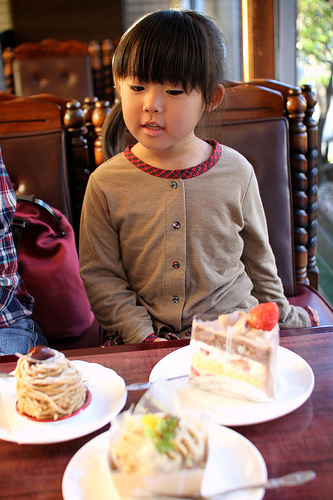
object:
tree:
[297, 0, 333, 162]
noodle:
[9, 348, 90, 415]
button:
[171, 180, 179, 191]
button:
[172, 221, 179, 230]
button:
[173, 261, 180, 270]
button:
[173, 295, 180, 303]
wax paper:
[187, 310, 282, 346]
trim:
[121, 139, 226, 182]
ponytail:
[102, 100, 127, 160]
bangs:
[115, 10, 211, 108]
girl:
[77, 7, 320, 344]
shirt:
[77, 137, 317, 347]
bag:
[13, 195, 112, 348]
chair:
[1, 94, 89, 249]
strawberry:
[245, 301, 279, 330]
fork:
[155, 467, 317, 499]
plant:
[60, 410, 267, 499]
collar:
[123, 134, 222, 181]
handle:
[12, 191, 62, 233]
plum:
[25, 346, 53, 366]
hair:
[100, 8, 232, 160]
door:
[242, 1, 281, 80]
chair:
[92, 83, 318, 295]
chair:
[1, 39, 102, 98]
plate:
[147, 342, 314, 424]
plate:
[0, 359, 130, 444]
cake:
[188, 301, 281, 403]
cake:
[9, 344, 85, 422]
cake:
[107, 411, 209, 498]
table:
[0, 328, 333, 500]